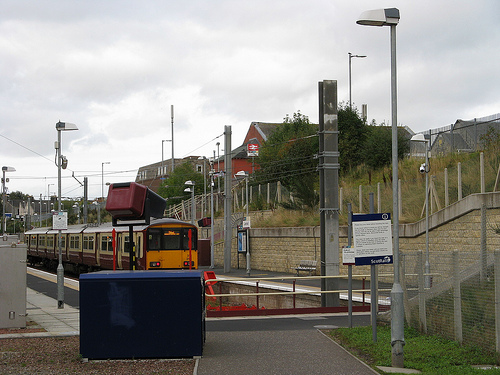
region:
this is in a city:
[25, 47, 405, 358]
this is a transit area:
[62, 112, 374, 369]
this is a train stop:
[29, 141, 323, 351]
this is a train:
[59, 200, 179, 280]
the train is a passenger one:
[76, 214, 212, 292]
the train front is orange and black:
[94, 204, 237, 298]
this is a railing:
[219, 268, 373, 348]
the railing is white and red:
[230, 273, 366, 343]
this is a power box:
[80, 264, 206, 346]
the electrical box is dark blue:
[81, 271, 243, 350]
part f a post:
[393, 292, 408, 317]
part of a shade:
[236, 296, 270, 350]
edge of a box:
[190, 292, 205, 329]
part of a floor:
[241, 298, 280, 368]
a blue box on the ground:
[75, 260, 204, 354]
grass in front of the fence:
[337, 322, 424, 372]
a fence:
[386, 249, 485, 322]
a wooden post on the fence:
[449, 247, 464, 346]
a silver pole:
[383, 40, 412, 359]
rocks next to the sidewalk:
[71, 358, 197, 373]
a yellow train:
[30, 217, 217, 271]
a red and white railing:
[211, 273, 413, 315]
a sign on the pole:
[51, 211, 72, 228]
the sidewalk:
[207, 313, 374, 374]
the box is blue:
[78, 269, 204, 359]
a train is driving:
[26, 220, 199, 283]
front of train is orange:
[142, 223, 196, 268]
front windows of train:
[148, 228, 195, 249]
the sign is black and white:
[352, 213, 392, 263]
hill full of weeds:
[252, 147, 497, 224]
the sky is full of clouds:
[0, 2, 494, 201]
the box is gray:
[1, 235, 28, 327]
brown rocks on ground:
[2, 336, 188, 373]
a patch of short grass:
[328, 327, 495, 372]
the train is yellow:
[145, 222, 196, 268]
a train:
[131, 218, 196, 268]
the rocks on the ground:
[11, 345, 57, 367]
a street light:
[347, 0, 407, 40]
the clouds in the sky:
[66, 40, 151, 88]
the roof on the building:
[251, 120, 276, 133]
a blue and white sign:
[355, 206, 396, 263]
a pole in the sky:
[162, 105, 192, 150]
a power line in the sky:
[16, 145, 41, 160]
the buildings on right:
[135, 107, 499, 190]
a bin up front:
[75, 267, 210, 359]